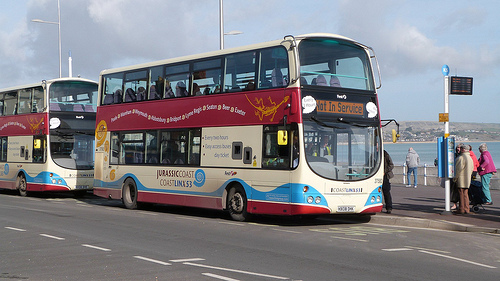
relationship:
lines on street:
[8, 219, 282, 281] [7, 186, 499, 280]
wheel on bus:
[226, 181, 250, 222] [95, 35, 387, 223]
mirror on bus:
[274, 128, 292, 147] [95, 35, 387, 223]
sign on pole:
[437, 135, 459, 182] [442, 74, 450, 210]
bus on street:
[95, 35, 387, 223] [7, 186, 499, 280]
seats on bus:
[112, 87, 159, 102] [95, 35, 387, 223]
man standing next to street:
[452, 144, 475, 217] [7, 186, 499, 280]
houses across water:
[405, 131, 442, 141] [379, 139, 499, 172]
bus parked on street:
[95, 35, 387, 223] [7, 186, 499, 280]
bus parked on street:
[3, 81, 97, 207] [7, 186, 499, 280]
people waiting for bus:
[451, 139, 496, 222] [95, 35, 387, 223]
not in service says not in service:
[314, 100, 364, 115] [317, 101, 364, 114]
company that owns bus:
[159, 178, 188, 188] [95, 35, 387, 223]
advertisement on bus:
[96, 94, 288, 131] [95, 35, 387, 223]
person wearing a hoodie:
[402, 145, 423, 188] [405, 152, 426, 173]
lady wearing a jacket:
[473, 143, 495, 203] [474, 151, 498, 173]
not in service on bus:
[314, 100, 364, 115] [95, 35, 387, 223]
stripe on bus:
[96, 187, 317, 213] [95, 35, 387, 223]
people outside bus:
[451, 139, 496, 222] [95, 35, 387, 223]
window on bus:
[159, 130, 187, 168] [95, 35, 387, 223]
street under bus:
[7, 186, 499, 280] [95, 35, 387, 223]